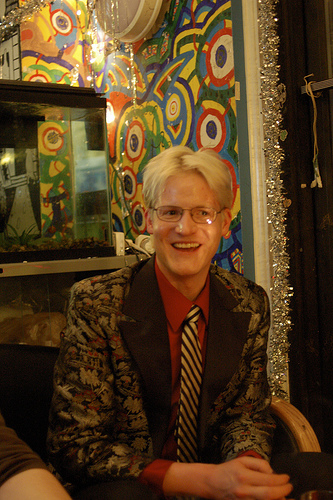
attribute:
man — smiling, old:
[50, 146, 293, 499]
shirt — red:
[143, 260, 261, 500]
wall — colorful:
[20, 2, 244, 276]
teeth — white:
[174, 242, 200, 249]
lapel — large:
[199, 275, 252, 459]